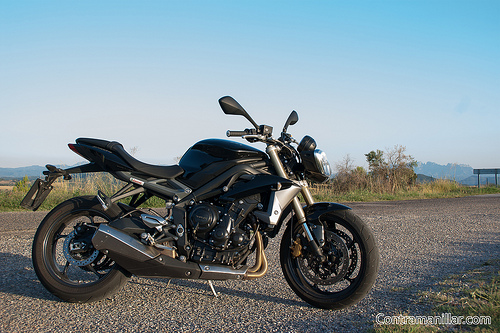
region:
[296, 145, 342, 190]
Headlight on front of motorcycle.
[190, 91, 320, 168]
Handle bars and rear view mirrors.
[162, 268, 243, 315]
Motorcycle kick stand.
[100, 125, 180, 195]
Seat on a motorcycle.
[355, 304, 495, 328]
White letters at bottom of picture.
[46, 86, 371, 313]
Motorcycle on the road.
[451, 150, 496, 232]
Sign by the road.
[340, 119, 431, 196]
Brown and green trees.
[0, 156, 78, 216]
Back part of a motorcycle.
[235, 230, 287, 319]
Two metal coils on motorcycle.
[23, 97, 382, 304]
The motorcycle is black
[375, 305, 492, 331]
The watermark is on right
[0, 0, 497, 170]
the sky is blue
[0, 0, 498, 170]
The sky is empty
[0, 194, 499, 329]
the road is gravel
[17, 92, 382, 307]
The motorcycle is on its kickstand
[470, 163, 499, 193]
There is a road sign on right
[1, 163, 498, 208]
The grass is green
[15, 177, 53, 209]
License plate is mounted to bike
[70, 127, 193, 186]
the seat is contour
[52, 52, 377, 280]
Motorcycle sitting on the road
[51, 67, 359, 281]
Black sports bike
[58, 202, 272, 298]
Muffler on the sport bike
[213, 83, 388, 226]
Headlight on the sport bike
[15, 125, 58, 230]
License plate holder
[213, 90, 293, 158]
Mirrors on the handle bars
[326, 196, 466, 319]
Gravel roadway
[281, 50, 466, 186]
Clear blue sky in the distance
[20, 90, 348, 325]
Sport bike parked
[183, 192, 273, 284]
Sport bike engine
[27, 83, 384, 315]
a motorcycle on a kickstand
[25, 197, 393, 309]
tires on a motorcycle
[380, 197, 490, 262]
a dirt road with small stones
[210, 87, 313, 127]
rearview mirrors on a motorcycle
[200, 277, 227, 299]
a motorcycle kickstand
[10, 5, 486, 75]
clear blue sky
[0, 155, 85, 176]
mountains in the background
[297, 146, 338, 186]
a motorcycle headlight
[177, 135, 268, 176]
a shiny gas tank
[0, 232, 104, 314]
a shadow on the ground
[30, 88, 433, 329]
black motorcycle on road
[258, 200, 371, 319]
front wheel of bike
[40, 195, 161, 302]
bike wheel of bike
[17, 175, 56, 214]
exhaust of bike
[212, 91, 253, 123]
right black side mirror of bike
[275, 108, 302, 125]
left black side mirror of bike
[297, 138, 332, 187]
front square head light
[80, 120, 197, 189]
curved cushion seat of bike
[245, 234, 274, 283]
coils of bike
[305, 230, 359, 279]
spoke of front wheel